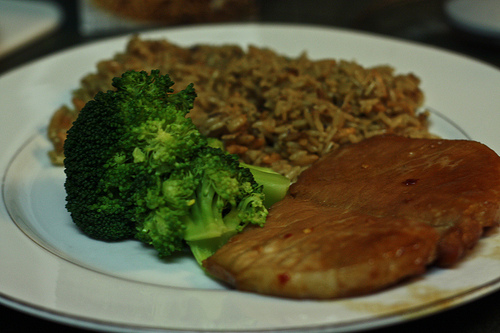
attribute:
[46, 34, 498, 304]
food — cooked, delicious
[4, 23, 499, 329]
plate — white, threequarter full, round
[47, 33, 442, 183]
rice — cooked, tan, brown, dry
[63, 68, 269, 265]
broccoli — chopped, green, very green, large chunk, steamed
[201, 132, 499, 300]
pork chop — light brown, brown, thin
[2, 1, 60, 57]
plate — white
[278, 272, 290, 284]
mark — red, spice